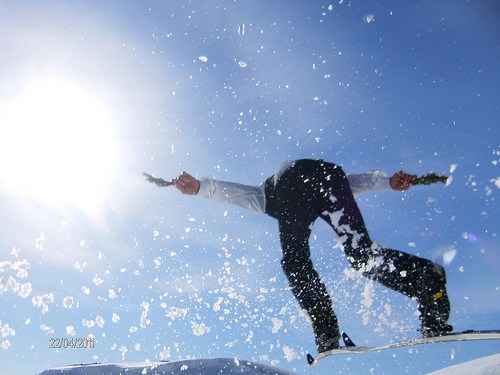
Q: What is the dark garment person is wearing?
A: Pants.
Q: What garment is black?
A: The pants.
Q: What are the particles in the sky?
A: Snow.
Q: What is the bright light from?
A: The sun.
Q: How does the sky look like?
A: Clear.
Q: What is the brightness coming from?
A: The sun.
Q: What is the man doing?
A: Skiing.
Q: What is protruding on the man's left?
A: A hand.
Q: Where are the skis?
A: In the air.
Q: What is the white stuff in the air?
A: Snow.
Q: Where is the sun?
A: In the sky.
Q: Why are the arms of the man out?
A: For balance.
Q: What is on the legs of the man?
A: Black pants.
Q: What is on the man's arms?
A: A white shirt.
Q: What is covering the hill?
A: Snow.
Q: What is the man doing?
A: Skiing.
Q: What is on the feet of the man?
A: Boots.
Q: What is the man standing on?
A: A snowboard.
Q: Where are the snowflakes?
A: In the air.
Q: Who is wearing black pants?
A: The snowboarder.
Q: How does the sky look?
A: Blue and clear.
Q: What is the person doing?
A: A trick on the snowboard.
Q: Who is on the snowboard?
A: The man.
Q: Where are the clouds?
A: In the sky.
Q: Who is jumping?
A: The snowboarder.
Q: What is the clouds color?
A: White.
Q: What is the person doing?
A: Skiing.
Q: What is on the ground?
A: Snow.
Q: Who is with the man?
A: No one.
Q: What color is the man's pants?
A: Black.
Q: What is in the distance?
A: Mountain.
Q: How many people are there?
A: One.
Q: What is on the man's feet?
A: Skis.